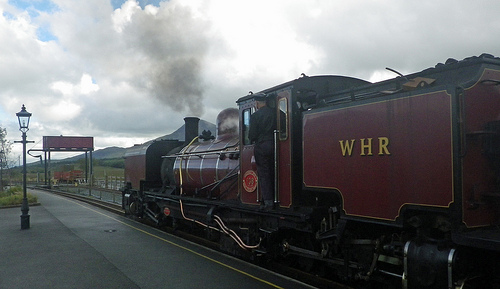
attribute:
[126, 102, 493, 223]
train — red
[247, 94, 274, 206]
engineer — standing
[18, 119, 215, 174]
mountains — ahead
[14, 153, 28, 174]
tank — ahead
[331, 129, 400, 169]
letters — yellow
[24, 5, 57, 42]
sky — cloudy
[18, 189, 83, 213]
sidewalk — concrete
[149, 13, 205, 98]
smoke — black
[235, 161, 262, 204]
sign — round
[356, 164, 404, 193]
paint — red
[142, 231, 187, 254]
line — yellow